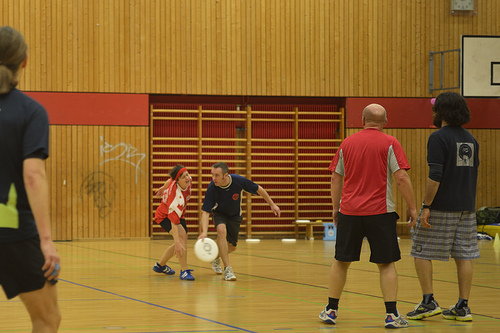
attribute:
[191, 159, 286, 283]
man — bending over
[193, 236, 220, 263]
frisbee — white, large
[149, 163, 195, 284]
woman — bending over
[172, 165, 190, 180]
headband — red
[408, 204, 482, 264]
shorts — striped, black, gray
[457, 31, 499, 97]
basketball goal — black, white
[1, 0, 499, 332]
gym — wood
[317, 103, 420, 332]
man — bald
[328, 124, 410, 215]
shirt — red, gray, blue, short-sleeved, white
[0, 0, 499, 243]
wall — light wood, wood paneling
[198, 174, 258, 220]
shirt — blue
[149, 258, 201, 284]
sneakers — blue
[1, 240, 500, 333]
floor — waxed, wood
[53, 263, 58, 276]
wrap — blue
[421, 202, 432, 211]
wristwatch — black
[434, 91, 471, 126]
hair — black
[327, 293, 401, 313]
socks — black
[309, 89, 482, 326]
men — watching